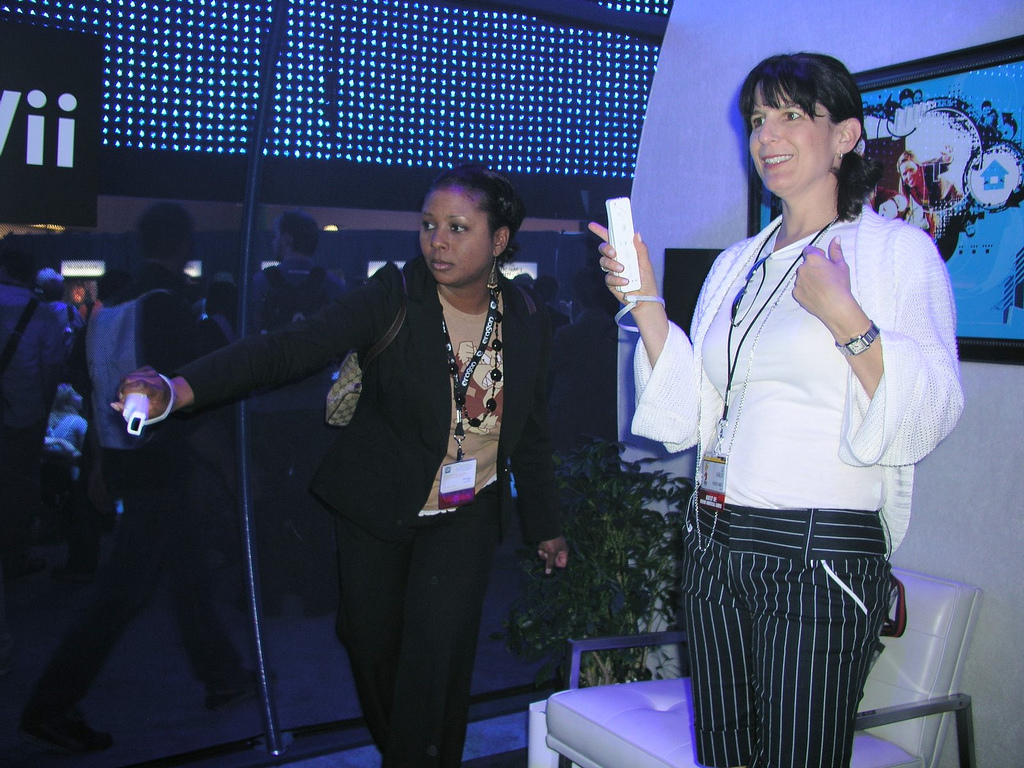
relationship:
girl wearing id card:
[109, 159, 574, 765] [437, 451, 477, 501]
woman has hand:
[588, 53, 964, 766] [792, 233, 853, 314]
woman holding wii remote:
[588, 53, 964, 766] [599, 194, 647, 307]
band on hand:
[141, 371, 178, 424] [113, 364, 176, 427]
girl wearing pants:
[110, 164, 568, 768] [329, 489, 502, 766]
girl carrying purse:
[110, 164, 568, 768] [318, 261, 411, 426]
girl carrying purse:
[110, 164, 568, 768] [321, 256, 415, 431]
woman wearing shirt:
[588, 53, 964, 766] [630, 207, 965, 545]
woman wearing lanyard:
[588, 53, 964, 766] [694, 217, 852, 509]